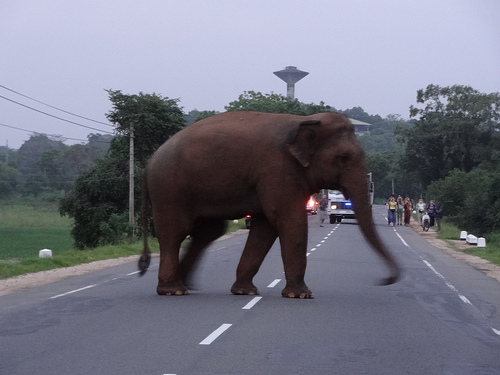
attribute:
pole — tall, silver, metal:
[121, 96, 141, 246]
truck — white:
[320, 168, 380, 224]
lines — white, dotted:
[192, 220, 354, 344]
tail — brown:
[135, 177, 153, 275]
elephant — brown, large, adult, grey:
[133, 108, 403, 298]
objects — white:
[457, 227, 484, 247]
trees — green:
[391, 79, 484, 225]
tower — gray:
[270, 64, 310, 95]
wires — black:
[0, 82, 127, 144]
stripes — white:
[195, 222, 351, 345]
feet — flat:
[156, 278, 313, 298]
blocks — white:
[455, 228, 484, 248]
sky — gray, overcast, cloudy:
[3, 2, 484, 152]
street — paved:
[5, 199, 484, 369]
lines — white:
[185, 270, 290, 360]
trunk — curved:
[342, 194, 405, 291]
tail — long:
[140, 198, 152, 281]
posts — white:
[448, 222, 492, 249]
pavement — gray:
[75, 309, 328, 372]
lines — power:
[6, 87, 122, 145]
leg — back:
[153, 233, 180, 295]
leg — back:
[184, 229, 222, 291]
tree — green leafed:
[400, 87, 498, 189]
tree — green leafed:
[426, 169, 498, 240]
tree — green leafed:
[59, 165, 145, 253]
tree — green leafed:
[106, 89, 186, 159]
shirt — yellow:
[389, 202, 396, 209]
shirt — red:
[403, 201, 410, 211]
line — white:
[197, 320, 227, 343]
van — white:
[326, 171, 374, 224]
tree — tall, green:
[61, 84, 184, 251]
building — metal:
[274, 64, 309, 101]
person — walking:
[382, 193, 402, 231]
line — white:
[193, 316, 240, 352]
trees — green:
[44, 78, 174, 259]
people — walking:
[382, 189, 438, 229]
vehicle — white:
[321, 182, 379, 220]